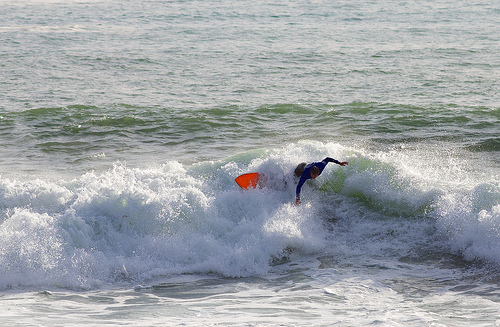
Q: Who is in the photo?
A: A man.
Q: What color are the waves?
A: White.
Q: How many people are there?
A: One.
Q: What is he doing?
A: Surfing.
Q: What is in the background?
A: Water.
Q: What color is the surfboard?
A: Orange.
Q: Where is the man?
A: In the ocean.